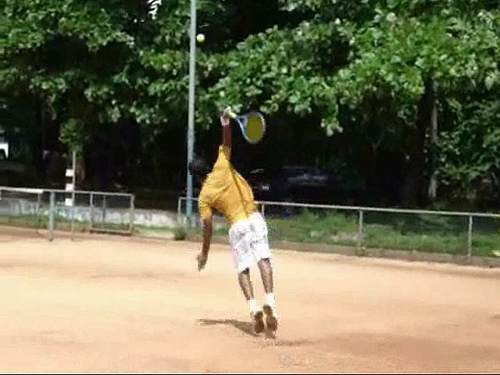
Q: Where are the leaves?
A: On the trees.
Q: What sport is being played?
A: Tennis.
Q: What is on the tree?
A: Green leaves.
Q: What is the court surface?
A: Clay dirt.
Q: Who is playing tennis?
A: The man with the yellow shirt.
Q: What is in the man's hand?
A: A tennis racket.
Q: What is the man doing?
A: Playing tennis.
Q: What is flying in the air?
A: The tennis ball.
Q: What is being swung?
A: A tennis racket.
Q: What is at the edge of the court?
A: A metal fence.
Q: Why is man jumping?
A: Hit ball.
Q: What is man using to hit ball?
A: Racket.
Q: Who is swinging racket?
A: Tennis player.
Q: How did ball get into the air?
A: It was hit.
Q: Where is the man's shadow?
A: Underneath him.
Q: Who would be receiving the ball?
A: Opponent.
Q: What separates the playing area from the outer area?
A: Fence.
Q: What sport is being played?
A: Tennis.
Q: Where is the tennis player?
A: In a tennis court.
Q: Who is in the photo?
A: A man.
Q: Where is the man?
A: Tennis Court.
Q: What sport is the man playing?
A: Tennis.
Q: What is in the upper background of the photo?
A: Trees.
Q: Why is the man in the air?
A: He jumped.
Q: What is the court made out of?
A: Dirt.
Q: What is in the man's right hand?
A: Tennis racquet.